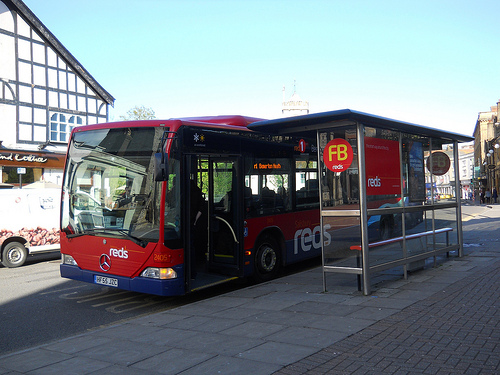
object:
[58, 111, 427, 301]
bus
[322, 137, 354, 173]
sign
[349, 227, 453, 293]
seat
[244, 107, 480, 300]
bus stop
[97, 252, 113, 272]
symbol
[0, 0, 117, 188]
building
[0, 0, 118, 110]
top half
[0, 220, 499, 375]
sidewalk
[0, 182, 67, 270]
vehicle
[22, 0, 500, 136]
sky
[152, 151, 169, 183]
mirror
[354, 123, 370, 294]
edge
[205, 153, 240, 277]
door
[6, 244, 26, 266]
rim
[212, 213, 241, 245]
handle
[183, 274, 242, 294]
edge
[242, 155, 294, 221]
window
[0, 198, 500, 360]
street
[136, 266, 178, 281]
headlight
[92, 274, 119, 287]
license plate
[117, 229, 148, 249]
wiper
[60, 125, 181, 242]
windshield